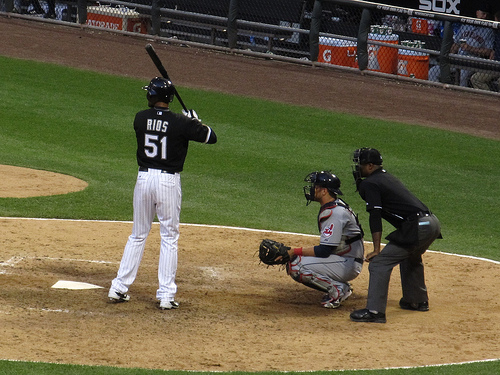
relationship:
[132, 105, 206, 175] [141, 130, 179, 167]
jersey has number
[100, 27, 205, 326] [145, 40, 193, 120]
batter holding bat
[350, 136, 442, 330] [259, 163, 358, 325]
umpire behind catcher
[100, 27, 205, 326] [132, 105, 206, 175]
batter wearing jersey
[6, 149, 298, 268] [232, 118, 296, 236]
field has grass